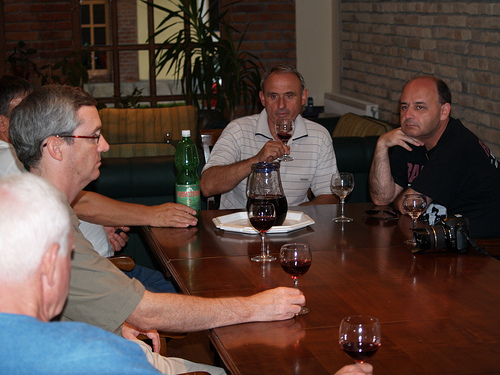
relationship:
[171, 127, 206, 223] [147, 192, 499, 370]
bottle on top of table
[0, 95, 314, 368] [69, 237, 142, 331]
man wearing shirt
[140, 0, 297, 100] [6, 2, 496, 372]
plant in back of restaurant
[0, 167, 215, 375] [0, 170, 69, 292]
man has white hair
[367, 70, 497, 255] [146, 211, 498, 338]
man on top of table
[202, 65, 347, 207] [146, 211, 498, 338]
man on top of table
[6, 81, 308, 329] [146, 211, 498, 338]
man on top of table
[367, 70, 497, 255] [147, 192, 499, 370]
man sitting on table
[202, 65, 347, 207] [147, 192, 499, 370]
man sitting on table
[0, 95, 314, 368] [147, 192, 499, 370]
man sitting on table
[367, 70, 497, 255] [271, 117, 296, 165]
man drinking wine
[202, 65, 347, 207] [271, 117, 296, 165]
man drinking wine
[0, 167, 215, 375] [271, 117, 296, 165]
man drinking wine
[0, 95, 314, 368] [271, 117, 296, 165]
man drinking wine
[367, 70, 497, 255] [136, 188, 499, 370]
man drinking at brown table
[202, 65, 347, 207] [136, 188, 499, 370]
man drinking at brown table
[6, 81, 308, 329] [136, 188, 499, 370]
man drinking at brown table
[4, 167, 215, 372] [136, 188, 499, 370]
man drinking at brown table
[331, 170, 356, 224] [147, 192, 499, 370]
wine glass on top of table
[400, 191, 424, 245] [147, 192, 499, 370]
glass on top of table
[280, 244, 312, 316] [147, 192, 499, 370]
glass on top of table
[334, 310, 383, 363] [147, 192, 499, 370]
glass on top of table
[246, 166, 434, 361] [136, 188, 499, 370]
wine glasses are on top of brown table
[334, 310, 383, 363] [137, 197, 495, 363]
glass are on top of table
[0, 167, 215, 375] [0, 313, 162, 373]
man wearing shirt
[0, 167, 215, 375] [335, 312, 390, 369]
man holding glass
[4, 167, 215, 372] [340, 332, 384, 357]
man holding wine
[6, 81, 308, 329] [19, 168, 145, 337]
man wearing shirt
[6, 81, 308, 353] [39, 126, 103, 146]
man wearing glasses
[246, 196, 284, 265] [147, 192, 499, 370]
glass sitting on top of table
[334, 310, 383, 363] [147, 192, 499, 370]
glass sitting on top of table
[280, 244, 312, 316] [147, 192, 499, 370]
glass sitting on top of table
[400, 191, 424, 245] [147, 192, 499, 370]
glass sitting on top of table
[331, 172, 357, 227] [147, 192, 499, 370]
glass sitting on top of table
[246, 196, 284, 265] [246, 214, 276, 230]
glass containing wine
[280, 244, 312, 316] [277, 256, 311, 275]
glass containing wine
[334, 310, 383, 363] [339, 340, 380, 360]
glass containing wine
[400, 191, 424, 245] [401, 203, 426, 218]
glass containing wine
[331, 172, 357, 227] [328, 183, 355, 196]
glass containing wine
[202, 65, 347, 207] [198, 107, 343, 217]
man wearing shirt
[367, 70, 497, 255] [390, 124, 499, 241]
man wearing shirt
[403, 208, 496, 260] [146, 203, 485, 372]
camera sitting on top of table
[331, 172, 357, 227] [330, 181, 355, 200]
glass containing wine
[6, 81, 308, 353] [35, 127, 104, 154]
man wearing glasses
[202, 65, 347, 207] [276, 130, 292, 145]
man drinking wine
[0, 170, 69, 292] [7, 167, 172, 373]
white hair belonging to man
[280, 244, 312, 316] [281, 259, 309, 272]
glass containing wine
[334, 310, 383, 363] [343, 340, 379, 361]
glass containing wine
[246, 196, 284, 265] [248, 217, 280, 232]
glass containing wine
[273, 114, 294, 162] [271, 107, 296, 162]
glass containing wine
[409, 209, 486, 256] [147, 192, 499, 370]
camera sitting on top of table